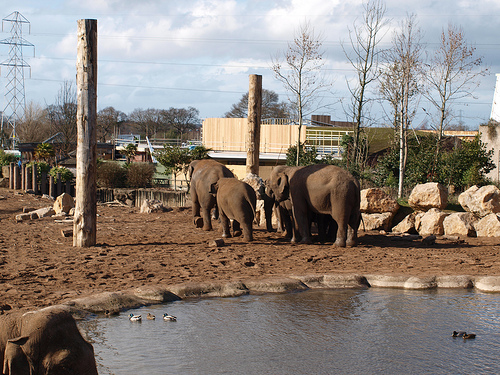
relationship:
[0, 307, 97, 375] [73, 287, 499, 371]
elephant drinking water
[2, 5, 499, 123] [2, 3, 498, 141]
clouds in sky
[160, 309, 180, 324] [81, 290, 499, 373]
duck in pond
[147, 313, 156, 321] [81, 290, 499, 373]
duck in pond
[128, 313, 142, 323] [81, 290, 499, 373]
duck in pond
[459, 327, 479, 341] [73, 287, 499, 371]
duck in water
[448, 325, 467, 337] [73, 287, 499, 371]
duck in water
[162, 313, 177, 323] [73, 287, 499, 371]
duck in water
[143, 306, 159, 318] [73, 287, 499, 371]
duck in water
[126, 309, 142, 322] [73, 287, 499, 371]
duck in water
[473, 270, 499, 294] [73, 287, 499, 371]
rock around water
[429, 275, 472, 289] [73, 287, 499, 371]
rock around water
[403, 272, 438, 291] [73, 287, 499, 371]
rock around water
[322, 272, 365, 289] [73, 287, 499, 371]
rock around water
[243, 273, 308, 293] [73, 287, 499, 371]
rock around water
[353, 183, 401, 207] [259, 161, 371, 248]
rock beside elephant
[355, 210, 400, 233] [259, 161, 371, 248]
rock beside elephant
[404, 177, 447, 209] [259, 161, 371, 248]
rock beside elephant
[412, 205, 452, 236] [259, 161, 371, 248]
rock beside elephant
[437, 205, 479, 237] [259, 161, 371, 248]
rock beside elephant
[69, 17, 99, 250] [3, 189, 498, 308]
stump rising from dirt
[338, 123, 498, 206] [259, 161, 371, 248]
bushes beside elephant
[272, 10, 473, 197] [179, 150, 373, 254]
trees by elephants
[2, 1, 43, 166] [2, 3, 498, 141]
pole in sky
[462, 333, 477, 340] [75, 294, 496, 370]
duck in water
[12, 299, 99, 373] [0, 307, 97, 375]
head of an elephant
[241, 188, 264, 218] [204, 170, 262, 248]
tail of an elephant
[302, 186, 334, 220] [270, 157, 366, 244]
stomach of an elephant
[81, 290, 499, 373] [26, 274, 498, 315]
pond surrounded by stones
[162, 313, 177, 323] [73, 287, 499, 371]
duck swimming on water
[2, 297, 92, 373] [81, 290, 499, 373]
elephant drinking from pond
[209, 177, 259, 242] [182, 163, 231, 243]
elephant walking behind an elephant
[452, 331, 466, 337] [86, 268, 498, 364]
duck swimming in water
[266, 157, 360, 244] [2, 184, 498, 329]
elephant walking on sand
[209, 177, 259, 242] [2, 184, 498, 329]
elephant walking on sand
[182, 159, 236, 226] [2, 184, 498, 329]
elephant walking on sand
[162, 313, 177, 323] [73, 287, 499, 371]
duck swimming in water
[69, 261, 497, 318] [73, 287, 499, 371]
barrier surrounding water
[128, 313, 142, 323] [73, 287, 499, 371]
duck swimming in water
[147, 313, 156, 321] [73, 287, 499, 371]
duck swimming in water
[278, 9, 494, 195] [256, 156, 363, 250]
trees beside elephant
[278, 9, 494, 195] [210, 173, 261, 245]
trees beside elephant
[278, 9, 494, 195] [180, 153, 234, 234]
trees beside elephant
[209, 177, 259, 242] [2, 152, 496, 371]
elephant in area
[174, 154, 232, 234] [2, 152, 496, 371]
elephant in area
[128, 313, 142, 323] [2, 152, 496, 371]
duck in area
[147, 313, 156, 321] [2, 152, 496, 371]
duck in area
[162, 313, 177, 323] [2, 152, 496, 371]
duck in area